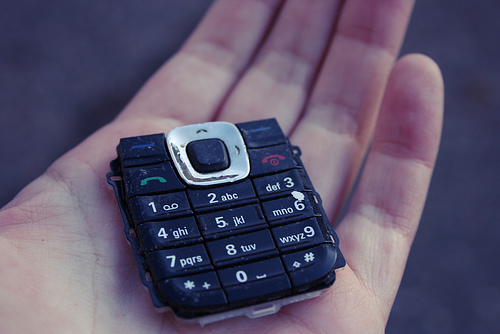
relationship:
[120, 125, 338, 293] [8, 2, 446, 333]
keypad in a hand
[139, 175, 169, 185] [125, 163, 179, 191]
phone handset on a button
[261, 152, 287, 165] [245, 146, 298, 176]
phone handset on a button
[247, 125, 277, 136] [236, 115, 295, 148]
line on right button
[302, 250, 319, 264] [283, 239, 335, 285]
number sign on bottom button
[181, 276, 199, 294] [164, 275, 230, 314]
asterisk sign on a button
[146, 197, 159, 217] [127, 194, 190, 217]
one on a button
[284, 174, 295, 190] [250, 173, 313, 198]
three on a button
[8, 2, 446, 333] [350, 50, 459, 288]
hand has a pinky finger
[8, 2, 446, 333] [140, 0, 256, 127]
hand has an index finger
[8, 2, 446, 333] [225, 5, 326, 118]
hand has a middle finger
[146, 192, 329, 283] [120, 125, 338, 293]
buttons are on a keypad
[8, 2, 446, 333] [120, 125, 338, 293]
hand holding keypad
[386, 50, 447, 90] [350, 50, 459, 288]
finger tip on a pinky finger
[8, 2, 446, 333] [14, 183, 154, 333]
hand has a palm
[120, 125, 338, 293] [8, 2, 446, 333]
keypad broken phone in hand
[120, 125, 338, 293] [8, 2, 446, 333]
keypad broken phone in a hand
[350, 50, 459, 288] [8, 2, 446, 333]
pinky finger part of a hand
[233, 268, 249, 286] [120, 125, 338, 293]
zero on a keypad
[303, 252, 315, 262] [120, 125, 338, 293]
number sign on a keypad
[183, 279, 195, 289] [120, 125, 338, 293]
asterisk sign on a keypad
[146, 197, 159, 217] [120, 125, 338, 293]
one on a keypad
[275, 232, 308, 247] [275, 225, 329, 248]
wxyz on a button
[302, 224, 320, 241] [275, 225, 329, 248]
nine on a button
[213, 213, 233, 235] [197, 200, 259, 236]
five on a button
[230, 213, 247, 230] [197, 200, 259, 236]
jkl on a button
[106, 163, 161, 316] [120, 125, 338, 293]
metal flange on side of keypad